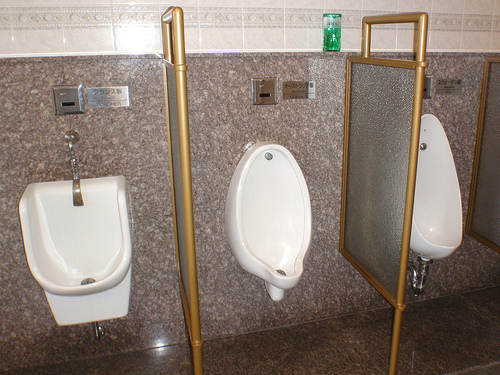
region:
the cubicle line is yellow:
[191, 305, 213, 355]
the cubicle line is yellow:
[194, 321, 204, 326]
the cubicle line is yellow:
[190, 321, 208, 348]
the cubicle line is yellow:
[194, 308, 205, 327]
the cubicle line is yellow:
[185, 283, 212, 316]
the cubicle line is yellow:
[192, 314, 211, 332]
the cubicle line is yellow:
[194, 336, 204, 341]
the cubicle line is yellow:
[193, 336, 207, 347]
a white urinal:
[204, 77, 351, 324]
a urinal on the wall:
[212, 110, 354, 359]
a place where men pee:
[216, 114, 326, 307]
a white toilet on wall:
[196, 98, 353, 330]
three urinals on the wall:
[5, 82, 490, 330]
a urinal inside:
[187, 68, 362, 348]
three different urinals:
[12, 74, 489, 356]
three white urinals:
[14, 61, 496, 338]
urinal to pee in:
[193, 86, 390, 339]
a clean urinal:
[175, 110, 370, 373]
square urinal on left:
[20, 126, 145, 337]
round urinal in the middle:
[215, 115, 317, 315]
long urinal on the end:
[392, 96, 470, 303]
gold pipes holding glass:
[345, 6, 423, 351]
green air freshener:
[312, 9, 351, 58]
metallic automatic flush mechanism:
[45, 80, 135, 117]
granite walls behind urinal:
[207, 116, 337, 337]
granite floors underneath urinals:
[37, 308, 487, 373]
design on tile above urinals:
[15, 3, 476, 39]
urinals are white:
[209, 121, 329, 321]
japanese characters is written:
[96, 93, 126, 107]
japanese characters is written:
[103, 100, 111, 107]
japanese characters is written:
[109, 96, 124, 108]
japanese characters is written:
[94, 95, 110, 101]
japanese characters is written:
[108, 98, 131, 106]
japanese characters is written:
[107, 96, 119, 100]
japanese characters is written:
[98, 96, 130, 126]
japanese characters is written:
[96, 91, 118, 116]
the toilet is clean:
[32, 174, 164, 357]